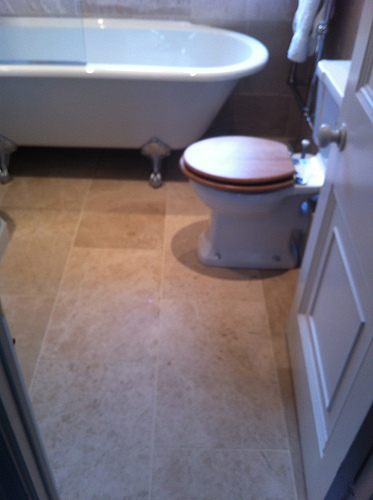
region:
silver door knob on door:
[315, 120, 347, 150]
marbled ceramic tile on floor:
[79, 359, 269, 497]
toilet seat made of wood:
[180, 134, 302, 194]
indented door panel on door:
[292, 200, 362, 457]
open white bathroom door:
[293, 85, 365, 488]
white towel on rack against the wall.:
[281, 0, 335, 62]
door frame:
[1, 299, 55, 498]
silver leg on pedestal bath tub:
[132, 137, 176, 191]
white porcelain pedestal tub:
[0, 19, 267, 188]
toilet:
[177, 60, 343, 275]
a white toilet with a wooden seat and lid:
[158, 109, 331, 285]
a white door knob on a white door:
[313, 119, 350, 149]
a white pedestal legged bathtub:
[7, 10, 277, 158]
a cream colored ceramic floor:
[40, 213, 188, 458]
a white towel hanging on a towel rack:
[287, 1, 337, 67]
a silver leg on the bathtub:
[129, 134, 172, 201]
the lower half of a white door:
[288, 189, 361, 460]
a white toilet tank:
[305, 51, 348, 121]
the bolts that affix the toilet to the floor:
[194, 239, 297, 277]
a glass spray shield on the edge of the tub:
[3, 2, 102, 80]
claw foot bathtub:
[0, 16, 269, 188]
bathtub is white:
[1, 18, 269, 186]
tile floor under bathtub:
[1, 93, 331, 499]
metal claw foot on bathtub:
[140, 136, 170, 188]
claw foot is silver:
[137, 138, 173, 185]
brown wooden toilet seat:
[176, 132, 298, 190]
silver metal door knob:
[316, 120, 348, 150]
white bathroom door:
[283, 51, 372, 497]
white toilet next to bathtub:
[179, 58, 330, 270]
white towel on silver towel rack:
[287, 2, 328, 129]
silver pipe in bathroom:
[283, 69, 314, 107]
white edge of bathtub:
[219, 54, 270, 79]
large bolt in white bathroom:
[211, 251, 230, 266]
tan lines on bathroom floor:
[50, 233, 98, 293]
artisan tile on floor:
[66, 366, 216, 439]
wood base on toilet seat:
[192, 176, 266, 194]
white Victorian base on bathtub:
[136, 139, 176, 184]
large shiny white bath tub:
[36, 5, 282, 110]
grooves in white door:
[318, 234, 371, 290]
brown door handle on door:
[316, 119, 353, 163]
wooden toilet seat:
[177, 135, 299, 192]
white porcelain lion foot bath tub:
[2, 13, 270, 153]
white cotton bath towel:
[286, 0, 326, 61]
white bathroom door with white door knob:
[288, 59, 369, 489]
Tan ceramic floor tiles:
[58, 300, 287, 498]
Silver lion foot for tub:
[136, 138, 178, 187]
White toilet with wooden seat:
[176, 57, 372, 274]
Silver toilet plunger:
[294, 135, 316, 218]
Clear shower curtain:
[0, 2, 125, 64]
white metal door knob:
[313, 122, 351, 150]